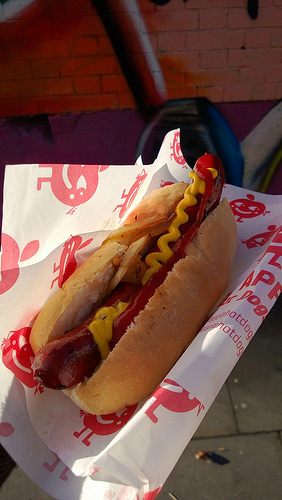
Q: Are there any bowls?
A: No, there are no bowls.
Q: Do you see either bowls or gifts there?
A: No, there are no bowls or gifts.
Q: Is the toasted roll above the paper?
A: Yes, the toilet roll is above the paper.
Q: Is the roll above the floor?
A: Yes, the roll is above the floor.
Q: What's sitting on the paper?
A: The toilet roll is sitting on the paper.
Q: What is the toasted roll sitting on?
A: The roll is sitting on the paper.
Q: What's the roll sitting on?
A: The roll is sitting on the paper.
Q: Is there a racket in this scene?
A: No, there are no rackets.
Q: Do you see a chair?
A: Yes, there is a chair.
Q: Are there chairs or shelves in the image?
A: Yes, there is a chair.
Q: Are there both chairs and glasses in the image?
A: No, there is a chair but no glasses.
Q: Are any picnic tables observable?
A: No, there are no picnic tables.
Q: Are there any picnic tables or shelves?
A: No, there are no picnic tables or shelves.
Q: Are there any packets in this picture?
A: No, there are no packets.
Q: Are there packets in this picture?
A: No, there are no packets.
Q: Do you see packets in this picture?
A: No, there are no packets.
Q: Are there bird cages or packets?
A: No, there are no packets or bird cages.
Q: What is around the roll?
A: The paper is around the roll.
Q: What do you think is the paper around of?
A: The paper is around the toilet roll.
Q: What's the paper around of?
A: The paper is around the toilet roll.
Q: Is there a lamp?
A: No, there are no lamps.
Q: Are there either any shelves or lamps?
A: No, there are no lamps or shelves.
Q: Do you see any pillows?
A: No, there are no pillows.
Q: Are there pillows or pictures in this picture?
A: No, there are no pillows or pictures.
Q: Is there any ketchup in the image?
A: Yes, there is ketchup.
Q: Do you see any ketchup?
A: Yes, there is ketchup.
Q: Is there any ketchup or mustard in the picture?
A: Yes, there is ketchup.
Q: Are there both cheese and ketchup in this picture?
A: No, there is ketchup but no cheese.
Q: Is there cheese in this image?
A: No, there is no cheese.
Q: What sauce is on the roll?
A: The sauce is ketchup.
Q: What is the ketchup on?
A: The ketchup is on the toilet roll.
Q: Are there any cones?
A: No, there are no cones.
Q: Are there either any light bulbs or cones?
A: No, there are no cones or light bulbs.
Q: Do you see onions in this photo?
A: Yes, there are onions.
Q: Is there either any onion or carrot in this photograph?
A: Yes, there are onions.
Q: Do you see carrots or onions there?
A: Yes, there are onions.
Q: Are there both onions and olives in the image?
A: No, there are onions but no olives.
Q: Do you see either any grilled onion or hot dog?
A: Yes, there are grilled onions.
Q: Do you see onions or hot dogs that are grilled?
A: Yes, the onions are grilled.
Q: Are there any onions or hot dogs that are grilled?
A: Yes, the onions are grilled.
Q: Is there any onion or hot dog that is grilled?
A: Yes, the onions are grilled.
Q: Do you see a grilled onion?
A: Yes, there are grilled onions.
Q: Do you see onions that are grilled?
A: Yes, there are onions that are grilled.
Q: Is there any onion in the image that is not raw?
A: Yes, there are grilled onions.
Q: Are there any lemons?
A: No, there are no lemons.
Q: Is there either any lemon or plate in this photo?
A: No, there are no lemons or plates.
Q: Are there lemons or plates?
A: No, there are no lemons or plates.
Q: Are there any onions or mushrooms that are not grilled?
A: No, there are onions but they are grilled.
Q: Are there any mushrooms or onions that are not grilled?
A: No, there are onions but they are grilled.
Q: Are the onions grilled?
A: Yes, the onions are grilled.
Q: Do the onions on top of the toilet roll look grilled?
A: Yes, the onions are grilled.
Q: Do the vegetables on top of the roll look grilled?
A: Yes, the onions are grilled.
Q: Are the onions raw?
A: No, the onions are grilled.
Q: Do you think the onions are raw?
A: No, the onions are grilled.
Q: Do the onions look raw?
A: No, the onions are grilled.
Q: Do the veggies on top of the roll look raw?
A: No, the onions are grilled.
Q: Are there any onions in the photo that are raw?
A: No, there are onions but they are grilled.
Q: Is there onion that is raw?
A: No, there are onions but they are grilled.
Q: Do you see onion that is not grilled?
A: No, there are onions but they are grilled.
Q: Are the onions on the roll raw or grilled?
A: The onions are grilled.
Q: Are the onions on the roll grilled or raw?
A: The onions are grilled.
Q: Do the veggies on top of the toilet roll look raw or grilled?
A: The onions are grilled.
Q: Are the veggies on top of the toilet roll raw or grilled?
A: The onions are grilled.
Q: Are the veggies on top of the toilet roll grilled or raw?
A: The onions are grilled.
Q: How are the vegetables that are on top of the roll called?
A: The vegetables are onions.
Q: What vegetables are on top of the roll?
A: The vegetables are onions.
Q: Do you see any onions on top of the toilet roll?
A: Yes, there are onions on top of the toilet roll.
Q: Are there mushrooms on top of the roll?
A: No, there are onions on top of the roll.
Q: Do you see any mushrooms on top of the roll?
A: No, there are onions on top of the roll.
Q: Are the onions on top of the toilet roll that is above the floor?
A: Yes, the onions are on top of the toilet roll.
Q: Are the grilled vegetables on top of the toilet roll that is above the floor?
A: Yes, the onions are on top of the toilet roll.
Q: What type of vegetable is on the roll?
A: The vegetables are onions.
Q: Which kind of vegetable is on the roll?
A: The vegetables are onions.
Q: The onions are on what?
A: The onions are on the roll.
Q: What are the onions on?
A: The onions are on the roll.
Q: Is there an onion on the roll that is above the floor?
A: Yes, there are onions on the toilet roll.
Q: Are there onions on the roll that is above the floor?
A: Yes, there are onions on the toilet roll.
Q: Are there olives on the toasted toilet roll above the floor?
A: No, there are onions on the roll.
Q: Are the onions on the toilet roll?
A: Yes, the onions are on the toilet roll.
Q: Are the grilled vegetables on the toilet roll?
A: Yes, the onions are on the toilet roll.